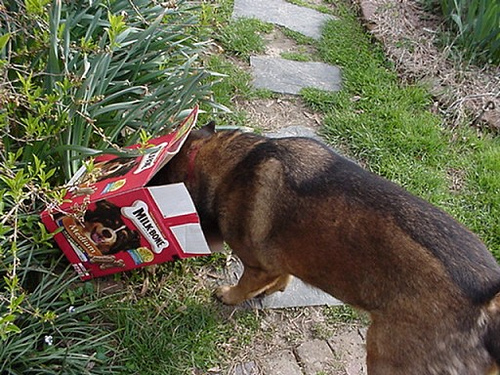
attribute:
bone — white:
[127, 190, 162, 260]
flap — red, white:
[143, 178, 215, 264]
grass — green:
[300, 0, 497, 250]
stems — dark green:
[90, 85, 148, 111]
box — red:
[38, 121, 200, 276]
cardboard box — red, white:
[40, 104, 211, 280]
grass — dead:
[378, 3, 438, 70]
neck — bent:
[185, 130, 260, 228]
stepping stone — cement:
[231, 1, 353, 310]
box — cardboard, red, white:
[36, 101, 226, 285]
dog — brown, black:
[171, 118, 498, 373]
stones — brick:
[231, 308, 368, 373]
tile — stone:
[229, 1, 337, 48]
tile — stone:
[246, 55, 346, 102]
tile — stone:
[261, 122, 329, 146]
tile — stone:
[234, 259, 346, 311]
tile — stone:
[298, 337, 343, 374]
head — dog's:
[81, 181, 146, 266]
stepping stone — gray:
[229, 0, 339, 43]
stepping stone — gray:
[239, 53, 351, 101]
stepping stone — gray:
[255, 120, 340, 154]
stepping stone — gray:
[250, 260, 354, 310]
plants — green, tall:
[32, 5, 134, 146]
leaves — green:
[0, 1, 150, 337]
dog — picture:
[78, 200, 143, 254]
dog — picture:
[79, 151, 132, 183]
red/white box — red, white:
[40, 100, 217, 280]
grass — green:
[98, 0, 498, 374]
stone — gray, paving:
[248, 54, 342, 95]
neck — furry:
[177, 114, 280, 255]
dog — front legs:
[137, 104, 492, 373]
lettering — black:
[134, 207, 167, 248]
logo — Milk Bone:
[124, 201, 173, 257]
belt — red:
[185, 143, 205, 186]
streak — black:
[260, 119, 494, 320]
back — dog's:
[184, 104, 491, 310]